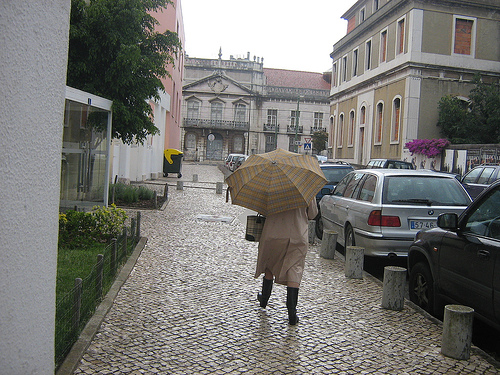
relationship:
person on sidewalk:
[259, 194, 319, 325] [53, 162, 495, 372]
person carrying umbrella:
[259, 194, 319, 325] [227, 149, 328, 216]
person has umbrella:
[259, 194, 319, 325] [227, 149, 328, 216]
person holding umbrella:
[259, 194, 319, 325] [227, 149, 328, 216]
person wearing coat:
[259, 194, 319, 325] [255, 195, 319, 287]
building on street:
[175, 58, 336, 169] [293, 159, 493, 368]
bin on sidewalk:
[163, 147, 182, 177] [53, 162, 495, 372]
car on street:
[318, 169, 478, 256] [293, 159, 493, 368]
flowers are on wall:
[405, 140, 453, 156] [403, 145, 499, 178]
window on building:
[452, 15, 478, 58] [327, 0, 494, 165]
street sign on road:
[302, 137, 313, 153] [293, 159, 493, 368]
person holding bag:
[259, 194, 319, 325] [245, 216, 267, 242]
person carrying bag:
[259, 194, 319, 325] [245, 216, 267, 242]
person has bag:
[259, 194, 319, 325] [245, 216, 267, 242]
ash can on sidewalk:
[163, 147, 182, 177] [53, 162, 495, 372]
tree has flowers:
[437, 89, 498, 143] [405, 140, 453, 156]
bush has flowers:
[58, 208, 122, 236] [58, 206, 122, 236]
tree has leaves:
[437, 89, 498, 143] [445, 103, 499, 140]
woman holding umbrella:
[259, 194, 319, 325] [227, 149, 328, 216]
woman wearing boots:
[259, 194, 319, 325] [257, 279, 300, 321]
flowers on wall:
[405, 140, 453, 156] [403, 145, 499, 178]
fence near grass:
[57, 207, 142, 363] [60, 233, 138, 363]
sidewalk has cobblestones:
[53, 162, 495, 372] [127, 331, 416, 374]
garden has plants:
[54, 207, 139, 370] [58, 208, 122, 236]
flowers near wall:
[405, 140, 453, 156] [403, 145, 499, 178]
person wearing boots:
[259, 194, 319, 325] [257, 279, 300, 321]